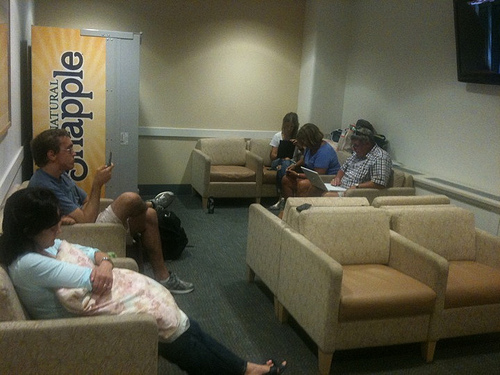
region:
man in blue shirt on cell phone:
[23, 118, 156, 230]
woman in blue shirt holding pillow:
[5, 186, 210, 343]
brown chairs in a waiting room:
[242, 197, 489, 324]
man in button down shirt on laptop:
[296, 125, 398, 197]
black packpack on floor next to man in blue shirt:
[98, 174, 211, 271]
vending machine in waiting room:
[26, 15, 153, 224]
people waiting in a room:
[1, 4, 489, 371]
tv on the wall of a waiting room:
[426, 2, 498, 77]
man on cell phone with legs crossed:
[22, 107, 222, 307]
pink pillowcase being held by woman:
[43, 209, 215, 363]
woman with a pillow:
[11, 190, 238, 374]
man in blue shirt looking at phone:
[23, 122, 182, 242]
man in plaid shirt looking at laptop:
[308, 124, 405, 206]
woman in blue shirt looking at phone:
[277, 121, 324, 192]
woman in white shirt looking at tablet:
[269, 107, 300, 164]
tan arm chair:
[292, 208, 439, 370]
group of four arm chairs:
[241, 194, 498, 356]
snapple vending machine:
[34, 21, 139, 198]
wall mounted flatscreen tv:
[443, 2, 498, 94]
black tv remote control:
[290, 196, 319, 231]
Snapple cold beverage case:
[27, 22, 157, 222]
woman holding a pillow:
[12, 180, 283, 372]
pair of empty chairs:
[284, 199, 498, 363]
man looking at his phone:
[27, 119, 199, 296]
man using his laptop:
[293, 118, 403, 210]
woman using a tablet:
[260, 105, 300, 205]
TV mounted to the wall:
[441, 0, 497, 98]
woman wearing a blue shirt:
[277, 114, 343, 194]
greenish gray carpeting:
[195, 218, 240, 296]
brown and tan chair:
[185, 129, 270, 221]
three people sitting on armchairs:
[230, 100, 421, 234]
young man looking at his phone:
[23, 126, 211, 298]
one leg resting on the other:
[106, 177, 216, 294]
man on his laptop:
[297, 118, 387, 215]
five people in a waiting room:
[1, 83, 481, 373]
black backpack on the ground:
[141, 203, 201, 268]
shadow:
[224, 278, 308, 370]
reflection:
[484, 21, 496, 64]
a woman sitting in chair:
[3, 184, 280, 372]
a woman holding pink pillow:
[0, 183, 285, 370]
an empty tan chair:
[275, 195, 442, 365]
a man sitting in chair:
[15, 124, 189, 298]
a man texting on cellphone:
[22, 124, 188, 293]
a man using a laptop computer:
[293, 114, 393, 204]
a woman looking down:
[275, 117, 336, 197]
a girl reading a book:
[267, 109, 299, 176]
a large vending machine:
[22, 20, 144, 208]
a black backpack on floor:
[130, 207, 191, 267]